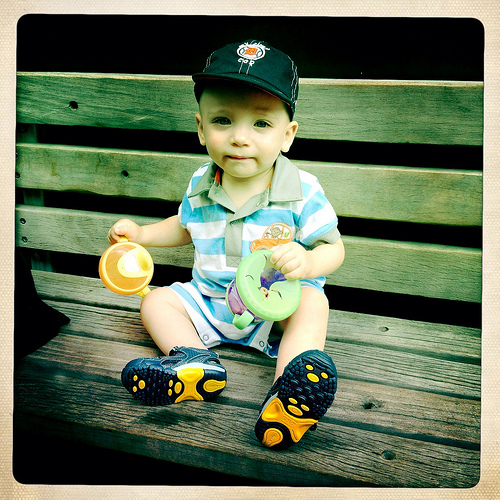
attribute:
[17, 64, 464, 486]
bench — wooden, old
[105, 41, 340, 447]
boy — little, sitting, young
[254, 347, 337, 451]
shoe — yellow, little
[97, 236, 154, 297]
sippy cup — plastic, yellow, clear, orange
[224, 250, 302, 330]
snack cup — plastic, green, purple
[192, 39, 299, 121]
baseball cap — orange, black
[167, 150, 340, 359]
onesie — striped, blue, white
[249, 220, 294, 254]
design — cartoon, embroidered, car, orange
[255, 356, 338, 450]
tread — black, yellow, rubber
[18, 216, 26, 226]
screws — metal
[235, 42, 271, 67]
logo — white, orange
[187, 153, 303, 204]
collar — tan